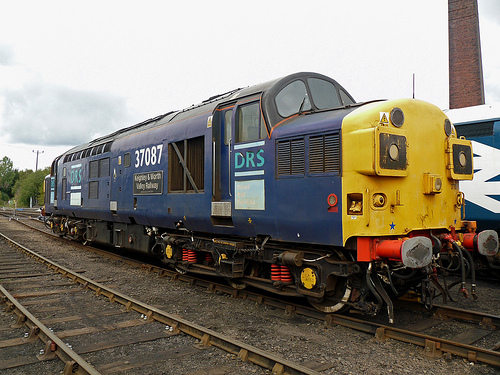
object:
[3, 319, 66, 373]
train tracks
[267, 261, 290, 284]
springs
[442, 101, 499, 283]
white train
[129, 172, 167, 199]
sign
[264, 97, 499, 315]
engine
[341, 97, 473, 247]
front end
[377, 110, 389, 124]
sticker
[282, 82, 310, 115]
windows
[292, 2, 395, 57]
sky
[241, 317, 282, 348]
rocks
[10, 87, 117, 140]
white cloud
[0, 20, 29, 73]
white cloud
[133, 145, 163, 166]
numbers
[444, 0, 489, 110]
smoke stack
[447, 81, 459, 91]
brick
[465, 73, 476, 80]
brick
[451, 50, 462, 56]
brick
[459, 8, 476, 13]
brick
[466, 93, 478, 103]
brick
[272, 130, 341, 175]
vent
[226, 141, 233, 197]
railings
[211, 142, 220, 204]
handle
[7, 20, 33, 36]
cloud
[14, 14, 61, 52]
sky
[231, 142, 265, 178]
letters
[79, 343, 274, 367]
tracks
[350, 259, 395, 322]
cords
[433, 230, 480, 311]
cords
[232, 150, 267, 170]
sign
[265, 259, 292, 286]
metal spring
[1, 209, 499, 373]
ground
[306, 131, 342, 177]
grate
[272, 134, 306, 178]
grate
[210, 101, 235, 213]
door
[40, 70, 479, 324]
engine car